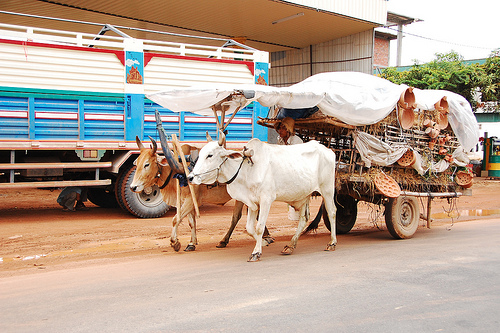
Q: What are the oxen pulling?
A: A wagon.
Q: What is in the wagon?
A: A variety of goods.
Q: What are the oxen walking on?
A: Tarmacked road.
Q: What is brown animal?
A: Cow.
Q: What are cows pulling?
A: Cart.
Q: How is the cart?
A: Parked.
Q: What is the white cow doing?
A: Walking.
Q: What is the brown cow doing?
A: Walking.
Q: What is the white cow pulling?
A: A cart.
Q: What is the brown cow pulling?
A: A cart.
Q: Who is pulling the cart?
A: The brown and white cow.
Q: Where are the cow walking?
A: On the road.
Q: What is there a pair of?
A: Cows.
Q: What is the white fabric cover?
A: The cart.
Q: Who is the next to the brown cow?
A: The white one.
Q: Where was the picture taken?
A: Street.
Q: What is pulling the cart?
A: Steer.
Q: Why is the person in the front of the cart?
A: Driving.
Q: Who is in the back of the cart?
A: Passengers.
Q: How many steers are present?
A: 2.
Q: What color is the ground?
A: Brown.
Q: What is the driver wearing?
A: Hat.